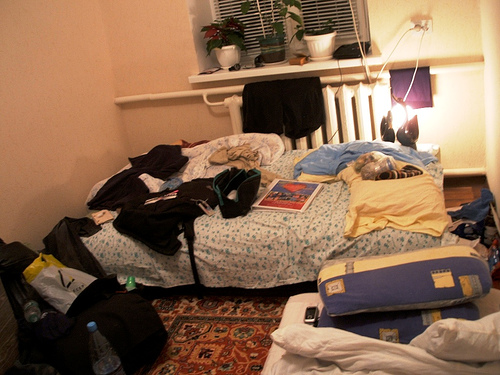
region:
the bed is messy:
[80, 135, 448, 286]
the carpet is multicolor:
[154, 288, 288, 373]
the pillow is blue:
[318, 245, 490, 320]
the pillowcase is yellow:
[341, 153, 454, 236]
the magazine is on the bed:
[253, 176, 324, 209]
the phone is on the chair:
[301, 303, 322, 320]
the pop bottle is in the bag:
[122, 274, 141, 292]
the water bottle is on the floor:
[84, 320, 119, 370]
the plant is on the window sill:
[201, 14, 246, 70]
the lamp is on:
[387, 70, 432, 135]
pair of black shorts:
[240, 78, 324, 139]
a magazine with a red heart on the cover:
[253, 176, 319, 211]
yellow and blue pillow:
[316, 244, 488, 314]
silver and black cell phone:
[305, 305, 318, 322]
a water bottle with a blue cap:
[85, 320, 121, 373]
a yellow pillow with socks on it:
[337, 155, 448, 234]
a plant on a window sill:
[200, 17, 245, 67]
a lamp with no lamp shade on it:
[379, 98, 419, 151]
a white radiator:
[223, 80, 393, 142]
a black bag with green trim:
[212, 168, 261, 218]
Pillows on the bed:
[317, 244, 490, 344]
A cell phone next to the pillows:
[303, 306, 319, 322]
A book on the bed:
[256, 175, 313, 208]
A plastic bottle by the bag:
[83, 320, 123, 373]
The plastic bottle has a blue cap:
[84, 321, 99, 331]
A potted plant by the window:
[205, 16, 245, 66]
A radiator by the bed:
[206, 75, 394, 151]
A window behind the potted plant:
[208, 1, 365, 55]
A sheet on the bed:
[81, 148, 440, 268]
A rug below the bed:
[109, 300, 289, 373]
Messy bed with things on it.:
[84, 134, 443, 283]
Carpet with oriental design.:
[171, 296, 260, 371]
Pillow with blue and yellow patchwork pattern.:
[318, 245, 487, 311]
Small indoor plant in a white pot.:
[203, 17, 245, 67]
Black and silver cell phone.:
[303, 304, 320, 324]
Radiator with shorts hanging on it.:
[216, 78, 393, 150]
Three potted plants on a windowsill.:
[196, 4, 338, 68]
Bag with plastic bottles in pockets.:
[66, 270, 165, 372]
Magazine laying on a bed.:
[254, 176, 324, 213]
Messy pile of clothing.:
[48, 141, 221, 250]